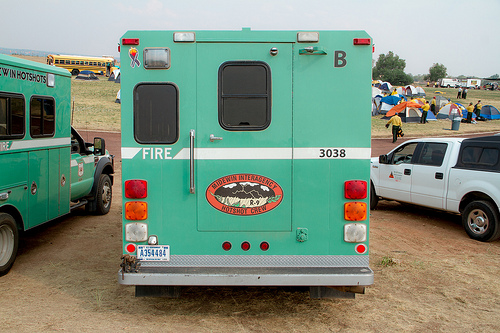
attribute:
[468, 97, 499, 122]
tent — blue 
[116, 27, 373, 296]
ambulance — aqua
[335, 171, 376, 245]
light — red 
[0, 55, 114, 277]
ambulance — aqua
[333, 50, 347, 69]
b — black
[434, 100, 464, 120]
tent — white, orange